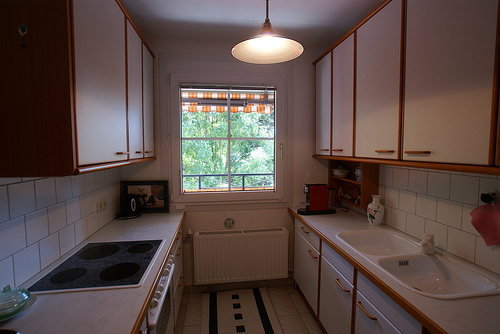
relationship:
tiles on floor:
[176, 276, 323, 332] [174, 273, 325, 329]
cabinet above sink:
[400, 2, 498, 170] [330, 221, 500, 298]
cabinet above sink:
[349, 3, 406, 158] [330, 221, 500, 298]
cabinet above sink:
[327, 23, 359, 153] [330, 221, 500, 298]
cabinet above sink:
[309, 50, 333, 157] [330, 221, 500, 298]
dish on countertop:
[366, 193, 386, 224] [290, 205, 498, 327]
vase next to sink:
[366, 193, 386, 224] [330, 221, 500, 298]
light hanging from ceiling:
[227, 0, 313, 71] [111, 5, 383, 67]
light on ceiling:
[227, 0, 313, 71] [111, 5, 383, 67]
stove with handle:
[147, 260, 182, 334] [149, 259, 180, 328]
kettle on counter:
[117, 189, 150, 220] [1, 209, 185, 329]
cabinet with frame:
[400, 2, 498, 170] [396, 4, 499, 175]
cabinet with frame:
[349, 3, 406, 158] [348, 4, 413, 166]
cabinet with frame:
[327, 23, 359, 153] [328, 23, 360, 165]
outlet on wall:
[96, 196, 110, 212] [4, 165, 125, 288]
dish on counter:
[1, 281, 39, 319] [1, 209, 185, 329]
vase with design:
[366, 193, 386, 224] [366, 205, 379, 224]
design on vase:
[366, 205, 379, 224] [366, 193, 386, 224]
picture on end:
[14, 22, 30, 56] [4, 4, 78, 177]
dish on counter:
[366, 193, 386, 224] [1, 209, 185, 329]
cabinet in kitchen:
[400, 2, 498, 170] [9, 4, 497, 332]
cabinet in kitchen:
[349, 3, 406, 158] [9, 4, 497, 332]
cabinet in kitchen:
[327, 23, 359, 153] [9, 4, 497, 332]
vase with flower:
[366, 193, 386, 224] [364, 200, 384, 215]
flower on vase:
[364, 200, 384, 215] [366, 193, 386, 224]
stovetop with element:
[37, 229, 160, 292] [99, 259, 140, 282]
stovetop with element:
[37, 229, 160, 292] [128, 236, 153, 256]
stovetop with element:
[37, 229, 160, 292] [46, 261, 91, 285]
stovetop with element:
[37, 229, 160, 292] [78, 240, 122, 259]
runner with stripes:
[201, 284, 287, 332] [208, 284, 276, 333]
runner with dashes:
[201, 284, 287, 332] [235, 287, 246, 331]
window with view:
[180, 88, 279, 191] [184, 95, 274, 185]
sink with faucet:
[330, 221, 500, 298] [412, 235, 447, 258]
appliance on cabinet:
[296, 180, 343, 216] [294, 221, 320, 299]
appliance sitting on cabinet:
[296, 180, 343, 216] [294, 221, 320, 299]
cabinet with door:
[400, 2, 498, 170] [404, 2, 497, 157]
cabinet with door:
[349, 3, 406, 158] [353, 4, 398, 155]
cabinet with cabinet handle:
[400, 2, 498, 170] [401, 150, 433, 156]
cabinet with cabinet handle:
[349, 3, 406, 158] [372, 148, 394, 154]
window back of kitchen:
[180, 88, 279, 191] [9, 4, 497, 332]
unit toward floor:
[195, 230, 288, 283] [174, 273, 325, 329]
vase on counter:
[366, 193, 386, 224] [1, 209, 185, 329]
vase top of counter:
[366, 193, 386, 224] [1, 209, 185, 329]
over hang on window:
[178, 88, 273, 114] [180, 88, 279, 191]